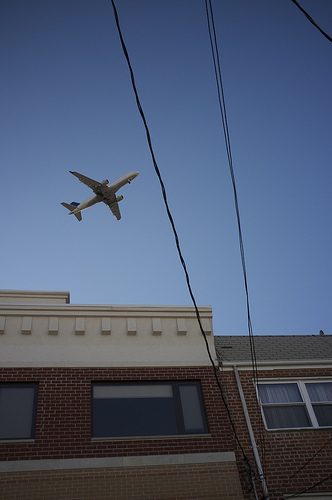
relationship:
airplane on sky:
[62, 166, 136, 221] [2, 1, 332, 305]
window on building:
[91, 379, 208, 437] [2, 288, 330, 499]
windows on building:
[245, 354, 330, 464] [65, 281, 307, 457]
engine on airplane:
[94, 180, 112, 191] [62, 166, 136, 221]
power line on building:
[114, 4, 237, 443] [2, 288, 330, 499]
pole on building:
[231, 365, 270, 499] [2, 288, 330, 499]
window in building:
[84, 378, 208, 437] [0, 289, 242, 498]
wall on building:
[1, 368, 227, 498] [4, 278, 238, 489]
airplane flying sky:
[60, 171, 139, 222] [192, 0, 332, 148]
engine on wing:
[95, 179, 109, 190] [61, 166, 110, 190]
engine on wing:
[103, 192, 122, 205] [100, 194, 120, 219]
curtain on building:
[257, 382, 313, 428] [1, 337, 233, 494]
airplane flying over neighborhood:
[60, 171, 139, 222] [8, 286, 314, 452]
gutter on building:
[211, 343, 329, 376] [220, 336, 323, 495]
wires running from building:
[106, 8, 300, 479] [11, 277, 318, 474]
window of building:
[246, 371, 330, 439] [2, 288, 330, 499]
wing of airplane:
[67, 163, 109, 189] [62, 166, 136, 221]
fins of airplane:
[60, 202, 81, 221] [62, 166, 136, 221]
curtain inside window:
[258, 382, 311, 427] [253, 374, 321, 430]